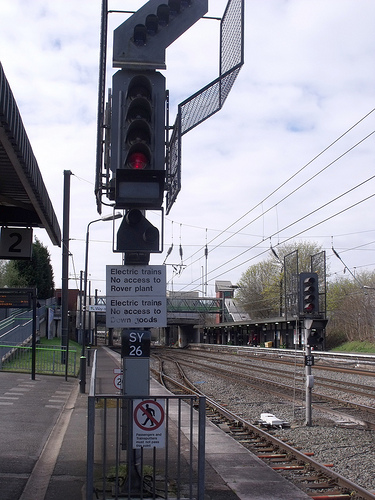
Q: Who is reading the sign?
A: The photographer.